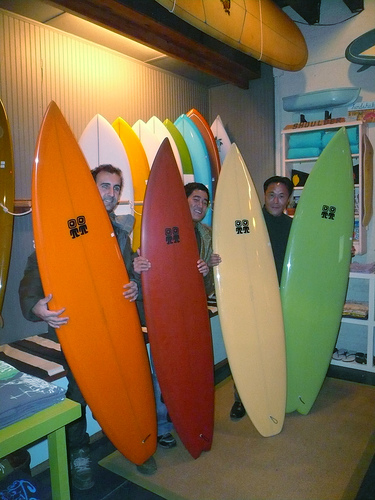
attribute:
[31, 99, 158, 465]
surfboard — orange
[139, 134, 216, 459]
surfboard — red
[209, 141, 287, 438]
surfboard — brown, white, beige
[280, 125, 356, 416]
surfboard — green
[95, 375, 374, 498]
mat — inside, brown, large, beige, green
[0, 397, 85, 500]
table — green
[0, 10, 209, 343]
wall — inside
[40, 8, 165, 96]
light — recessed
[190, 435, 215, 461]
tail — notched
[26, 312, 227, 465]
cabinet — blue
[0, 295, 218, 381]
cushion — striped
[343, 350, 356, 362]
shoe — white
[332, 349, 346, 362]
shoe — white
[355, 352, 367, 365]
shoe — black